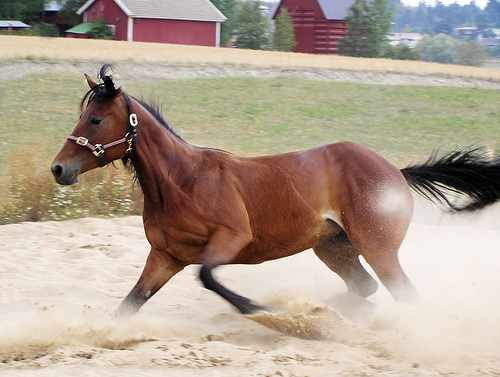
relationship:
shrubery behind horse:
[234, 10, 284, 41] [32, 49, 460, 343]